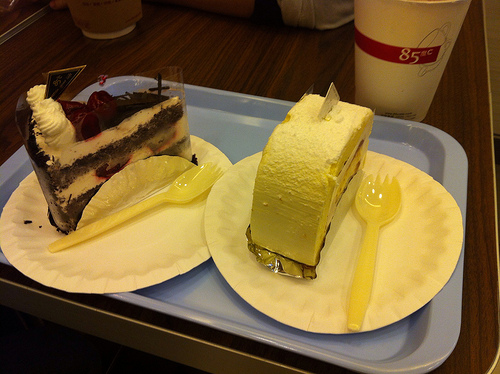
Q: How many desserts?
A: Two.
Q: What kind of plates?
A: Paper.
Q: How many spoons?
A: Two.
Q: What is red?
A: Banner on cup.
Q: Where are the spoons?
A: On the tray.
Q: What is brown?
A: Table.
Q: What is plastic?
A: Tray.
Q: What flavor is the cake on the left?
A: Chocolate.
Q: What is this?
A: Cake.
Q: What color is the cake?
A: Brown.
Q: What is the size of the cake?
A: Big.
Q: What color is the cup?
A: White.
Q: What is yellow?
A: The spork.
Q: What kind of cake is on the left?
A: Chocolate layered.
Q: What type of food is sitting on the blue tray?
A: Cake.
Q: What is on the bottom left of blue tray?
A: Paper plate.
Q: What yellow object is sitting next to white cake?
A: Spoon.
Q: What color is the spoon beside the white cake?
A: Cream.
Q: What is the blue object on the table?
A: A tray.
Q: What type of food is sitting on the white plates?
A: Cake.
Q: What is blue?
A: Tray.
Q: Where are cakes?
A: On plates.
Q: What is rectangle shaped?
A: The tray.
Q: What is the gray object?
A: A tray.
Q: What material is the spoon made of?
A: Plastic.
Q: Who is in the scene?
A: No one.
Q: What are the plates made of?
A: Paper.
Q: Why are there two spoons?
A: Two people are going to eat the food.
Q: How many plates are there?
A: Two.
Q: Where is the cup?
A: By the tray.